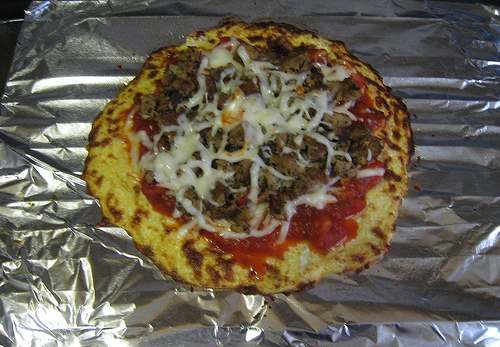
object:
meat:
[341, 125, 371, 145]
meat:
[165, 52, 197, 79]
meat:
[257, 187, 293, 219]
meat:
[278, 47, 313, 76]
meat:
[324, 75, 357, 100]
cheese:
[225, 95, 289, 139]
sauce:
[132, 187, 182, 219]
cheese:
[157, 130, 202, 184]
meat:
[152, 47, 183, 117]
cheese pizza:
[82, 22, 405, 295]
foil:
[14, 9, 485, 345]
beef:
[285, 40, 310, 62]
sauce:
[300, 214, 347, 242]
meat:
[352, 134, 382, 163]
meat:
[270, 187, 293, 211]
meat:
[232, 159, 248, 186]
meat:
[160, 76, 196, 96]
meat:
[265, 40, 299, 62]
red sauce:
[207, 210, 418, 281]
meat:
[144, 57, 195, 107]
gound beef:
[290, 125, 345, 175]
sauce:
[110, 103, 162, 132]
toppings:
[137, 40, 379, 241]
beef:
[339, 112, 387, 167]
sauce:
[181, 55, 386, 245]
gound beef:
[140, 167, 159, 187]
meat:
[202, 158, 257, 221]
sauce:
[294, 204, 360, 256]